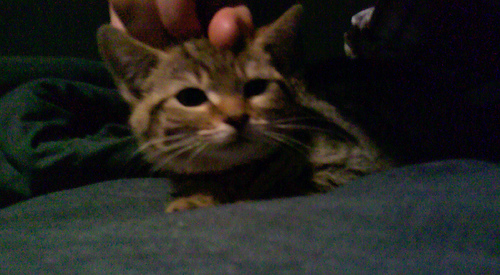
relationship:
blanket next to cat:
[0, 29, 160, 210] [90, 3, 397, 215]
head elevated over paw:
[87, 8, 309, 176] [156, 190, 215, 211]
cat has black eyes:
[90, 3, 397, 215] [171, 85, 209, 109]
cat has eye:
[90, 3, 397, 215] [240, 70, 271, 100]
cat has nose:
[90, 3, 397, 215] [223, 102, 247, 123]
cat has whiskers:
[106, 17, 388, 179] [128, 115, 329, 176]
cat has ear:
[90, 3, 397, 215] [88, 19, 165, 104]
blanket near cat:
[6, 29, 161, 210] [90, 3, 397, 215]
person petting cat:
[102, 2, 305, 82] [90, 3, 397, 215]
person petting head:
[102, 2, 305, 82] [128, 34, 290, 175]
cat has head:
[90, 3, 397, 215] [128, 34, 290, 175]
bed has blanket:
[4, 130, 484, 265] [7, 39, 168, 212]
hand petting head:
[108, 0, 285, 52] [40, 12, 401, 211]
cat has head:
[90, 3, 397, 215] [40, 12, 401, 211]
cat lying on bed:
[90, 3, 397, 215] [5, 158, 499, 271]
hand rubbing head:
[108, 0, 285, 52] [102, 25, 319, 183]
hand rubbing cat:
[108, 0, 285, 52] [90, 3, 397, 215]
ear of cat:
[95, 23, 169, 100] [90, 3, 397, 215]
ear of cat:
[256, 3, 303, 54] [90, 3, 397, 215]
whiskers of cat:
[126, 130, 212, 173] [90, 3, 397, 215]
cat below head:
[90, 3, 397, 215] [96, 0, 388, 213]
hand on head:
[108, 0, 285, 42] [87, 25, 287, 158]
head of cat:
[87, 25, 287, 158] [90, 3, 397, 215]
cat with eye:
[90, 3, 397, 215] [239, 78, 265, 97]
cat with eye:
[90, 3, 397, 215] [174, 77, 204, 107]